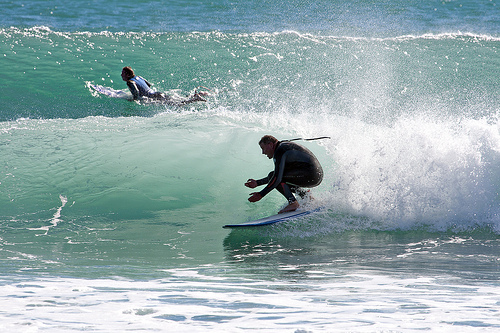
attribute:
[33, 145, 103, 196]
ripples — Small 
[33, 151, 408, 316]
water — rippled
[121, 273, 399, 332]
ripples — Small 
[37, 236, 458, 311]
water — cool 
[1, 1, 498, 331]
waves — wild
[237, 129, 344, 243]
wet suit — black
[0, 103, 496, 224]
wave — crashing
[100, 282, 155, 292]
ripple — Small 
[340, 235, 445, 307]
water — rippled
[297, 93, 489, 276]
waves — white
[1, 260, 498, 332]
foam — white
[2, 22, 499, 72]
wave — forming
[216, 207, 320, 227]
surfboard — blue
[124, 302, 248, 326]
ripple — Small 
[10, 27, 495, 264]
wave — wild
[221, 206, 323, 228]
board — blue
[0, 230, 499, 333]
ripples — small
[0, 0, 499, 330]
water — rippled, white, green